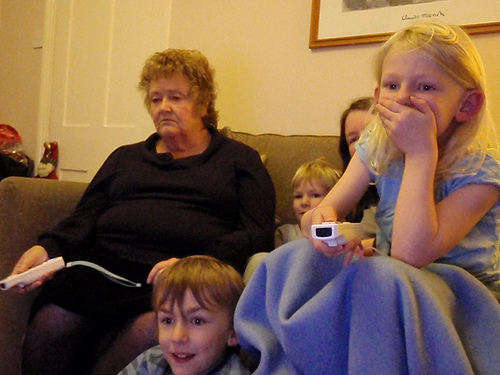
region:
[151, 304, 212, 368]
a face of a boy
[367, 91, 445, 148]
a hand over a mouth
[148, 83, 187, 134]
a face of a woman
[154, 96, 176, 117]
a nose on a face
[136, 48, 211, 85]
blonde curly hair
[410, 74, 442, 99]
an eye on a face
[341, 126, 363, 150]
an eye on a face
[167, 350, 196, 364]
a mouth on a face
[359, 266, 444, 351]
a purple fleece blanket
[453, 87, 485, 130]
an ear on a head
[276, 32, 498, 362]
little girl holding wiimote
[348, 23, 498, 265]
blond girl with hand over her mouth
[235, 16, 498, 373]
little girl wearing purple dress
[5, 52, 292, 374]
old woman holding wiimote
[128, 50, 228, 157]
old brunette woman frowning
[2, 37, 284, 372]
old woman wearing all black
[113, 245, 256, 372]
little brown haired boy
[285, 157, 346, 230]
little blond haired boy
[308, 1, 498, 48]
white picture in brown fram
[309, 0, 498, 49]
white picture with signature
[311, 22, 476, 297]
A girl covers her mouth with her hand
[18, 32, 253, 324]
A woman holds a white wii controller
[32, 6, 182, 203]
A white door with a puppet hanging off the handle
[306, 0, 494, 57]
A picture with a brown frame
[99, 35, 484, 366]
Three kids sit on the couch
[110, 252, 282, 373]
A boy with brown hair sits on the floor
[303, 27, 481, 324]
The girl in the blue dress holds a wii controller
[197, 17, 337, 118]
The walls are beige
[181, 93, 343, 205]
The couch is brown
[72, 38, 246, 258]
A woman in a black sweatshirt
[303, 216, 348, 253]
A wii remote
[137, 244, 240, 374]
A boy sitting on floor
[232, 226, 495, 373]
A purple blanket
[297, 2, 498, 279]
A girl covering her mouth with hand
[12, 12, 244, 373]
An older woman playing wii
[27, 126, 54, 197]
A santa on door handle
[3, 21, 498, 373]
a family bonding with each other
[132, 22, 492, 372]
Four children having fun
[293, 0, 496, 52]
Bottom corner of a painting on a wall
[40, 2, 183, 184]
A white door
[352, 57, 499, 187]
The girl has her hand on her mouth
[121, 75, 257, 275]
The woman has a dark shirt on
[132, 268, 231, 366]
The child is smiling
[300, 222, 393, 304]
The girl has a Wii remote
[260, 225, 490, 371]
The little girl has a blanket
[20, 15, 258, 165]
The door is white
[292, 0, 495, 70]
There is a picture behind the sofa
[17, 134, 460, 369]
The people are sitting on the couch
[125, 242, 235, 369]
The boy is blonde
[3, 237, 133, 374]
The woman is playing a game